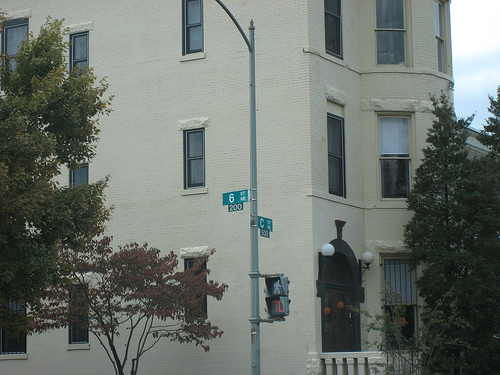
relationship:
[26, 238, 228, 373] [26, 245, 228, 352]
tree with foliage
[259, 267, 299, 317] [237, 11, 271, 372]
traffic sign on pole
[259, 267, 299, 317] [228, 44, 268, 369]
traffic sign on pole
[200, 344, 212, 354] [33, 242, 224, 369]
bloom on a tree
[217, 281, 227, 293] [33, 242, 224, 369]
bloom on a tree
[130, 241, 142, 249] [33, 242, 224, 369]
bloom on a tree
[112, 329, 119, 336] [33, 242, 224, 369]
bloom on a tree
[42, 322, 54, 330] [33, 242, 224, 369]
bloom on a tree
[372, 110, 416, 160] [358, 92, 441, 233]
blind in window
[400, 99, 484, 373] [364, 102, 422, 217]
tree right of blind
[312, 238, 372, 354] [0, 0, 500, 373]
doorway on building